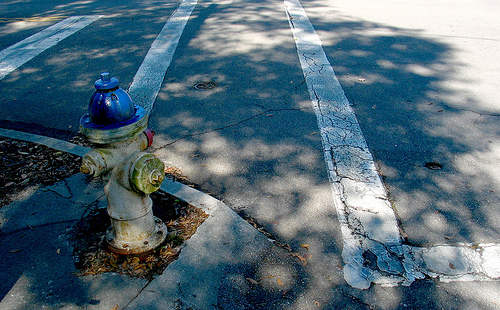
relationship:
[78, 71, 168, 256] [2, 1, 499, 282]
hydrant by street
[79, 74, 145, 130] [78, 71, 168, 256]
cap of hydrant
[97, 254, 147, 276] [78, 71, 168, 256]
leaves by hydrant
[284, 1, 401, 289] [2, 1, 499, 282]
line in street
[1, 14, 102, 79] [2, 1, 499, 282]
line in street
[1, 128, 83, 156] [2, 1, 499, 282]
burb by street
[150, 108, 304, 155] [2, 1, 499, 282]
crack in street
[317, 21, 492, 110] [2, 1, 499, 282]
shadow on street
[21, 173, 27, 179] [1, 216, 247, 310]
rock on sidewalk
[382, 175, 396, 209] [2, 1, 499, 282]
weeds on street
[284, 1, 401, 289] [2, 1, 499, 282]
line on street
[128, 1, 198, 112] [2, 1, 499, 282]
line in street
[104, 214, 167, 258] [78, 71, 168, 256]
base of hydrant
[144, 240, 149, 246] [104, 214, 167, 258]
bolt on base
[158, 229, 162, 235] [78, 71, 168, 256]
bolt on hydrant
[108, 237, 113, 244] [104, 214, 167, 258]
bolt on base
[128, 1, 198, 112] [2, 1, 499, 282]
line on street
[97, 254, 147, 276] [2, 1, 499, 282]
leaves on street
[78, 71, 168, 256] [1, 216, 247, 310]
hydrant on sidewalk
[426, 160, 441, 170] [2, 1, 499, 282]
hole in street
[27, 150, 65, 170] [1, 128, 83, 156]
leaves on burb